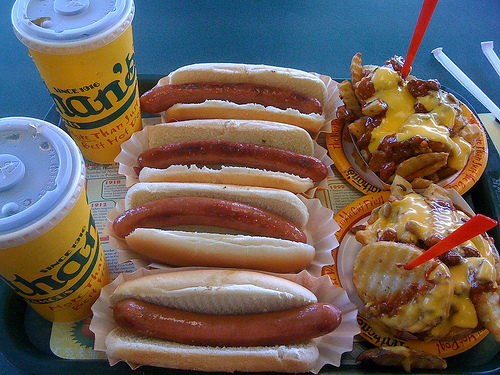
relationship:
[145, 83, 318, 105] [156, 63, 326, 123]
hot dog inside buns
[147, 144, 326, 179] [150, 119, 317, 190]
hot dog inside buns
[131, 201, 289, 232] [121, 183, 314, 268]
hot dog inside buns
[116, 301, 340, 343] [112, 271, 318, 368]
hot dog inside buns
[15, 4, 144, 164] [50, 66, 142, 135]
cup has writing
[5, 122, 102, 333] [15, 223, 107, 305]
cup has writing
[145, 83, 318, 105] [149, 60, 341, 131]
hot dog inside white wrapper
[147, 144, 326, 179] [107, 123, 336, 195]
hot dog inside white wrapper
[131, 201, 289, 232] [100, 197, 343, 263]
hot dog inside white wrapper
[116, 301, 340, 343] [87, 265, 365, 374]
hot dog inside white wrapper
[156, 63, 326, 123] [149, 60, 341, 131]
buns inside white wrapper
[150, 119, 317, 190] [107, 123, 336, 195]
buns inside white wrapper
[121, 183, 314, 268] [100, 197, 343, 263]
buns inside white wrapper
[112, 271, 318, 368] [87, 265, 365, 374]
buns inside white wrapper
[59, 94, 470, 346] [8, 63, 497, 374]
food and drinks are on top of a tray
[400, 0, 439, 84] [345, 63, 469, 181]
fork stuck inside chilli fries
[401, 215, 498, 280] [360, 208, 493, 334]
fork stuck inside chilli fries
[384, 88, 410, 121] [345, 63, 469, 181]
cheese drizzled on top chilli fries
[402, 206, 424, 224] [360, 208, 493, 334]
cheese drizzled on top chilli fries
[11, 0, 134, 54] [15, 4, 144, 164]
lid on top of a cup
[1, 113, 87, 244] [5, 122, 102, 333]
lid on top of a cup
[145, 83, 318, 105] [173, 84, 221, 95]
hot dog has grill marks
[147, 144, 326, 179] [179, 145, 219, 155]
hot dog has grill marks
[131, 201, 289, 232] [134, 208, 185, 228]
hot dog has grill marks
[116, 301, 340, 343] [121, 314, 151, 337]
hot dog has grill marks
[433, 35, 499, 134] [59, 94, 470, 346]
straw wrappers are to right of food and drinks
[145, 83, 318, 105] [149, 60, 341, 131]
hot dog are on top of white wrapper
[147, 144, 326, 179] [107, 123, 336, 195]
hot dog are on top of white wrapper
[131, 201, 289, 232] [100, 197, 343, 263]
hot dog are on top of white wrapper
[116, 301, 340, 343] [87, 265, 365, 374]
hot dog are on top of white wrapper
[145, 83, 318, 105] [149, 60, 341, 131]
hot dog on top of white wrapper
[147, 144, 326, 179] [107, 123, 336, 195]
hot dog on top of white wrapper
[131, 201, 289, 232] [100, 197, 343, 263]
hot dog on top of white wrapper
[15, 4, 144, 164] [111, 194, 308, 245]
cup to left of hot dog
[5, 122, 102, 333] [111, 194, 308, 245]
cup to left of hot dog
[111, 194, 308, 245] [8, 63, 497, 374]
hot dog are on tray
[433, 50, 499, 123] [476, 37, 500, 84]
straw to left of straw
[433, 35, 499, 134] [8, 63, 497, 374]
straw wrappers are to right of tray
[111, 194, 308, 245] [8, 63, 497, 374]
hot dog are on top of a tray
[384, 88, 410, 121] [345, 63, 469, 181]
cheese are drizzled on top chilli fries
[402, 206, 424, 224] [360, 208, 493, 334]
cheese are drizzled on top chilli fries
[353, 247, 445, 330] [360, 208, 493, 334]
potato slice next to chilli fries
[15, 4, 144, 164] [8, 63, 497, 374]
cup on top of tray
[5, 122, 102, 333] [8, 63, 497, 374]
cup on top of tray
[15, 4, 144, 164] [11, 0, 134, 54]
cup has lid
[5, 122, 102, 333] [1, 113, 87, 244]
cup has lid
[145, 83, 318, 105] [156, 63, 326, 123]
hot dog resting on to of buns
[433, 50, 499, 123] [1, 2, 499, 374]
straw on top of table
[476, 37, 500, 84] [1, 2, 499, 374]
straw on top of table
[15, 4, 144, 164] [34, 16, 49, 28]
cup filled with soda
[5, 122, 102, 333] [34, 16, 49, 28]
cup filled with soda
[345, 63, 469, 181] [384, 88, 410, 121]
chilli fries covered with cheese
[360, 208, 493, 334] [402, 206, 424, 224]
chilli fries covered with cheese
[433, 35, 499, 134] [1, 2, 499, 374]
straw wrappers are on table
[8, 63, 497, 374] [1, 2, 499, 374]
tray on table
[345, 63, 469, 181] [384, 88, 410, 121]
chilli fries are covered in cheese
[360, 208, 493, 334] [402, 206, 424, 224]
chilli fries are covered in cheese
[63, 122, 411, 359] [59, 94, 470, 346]
paper menu underneath food and drinks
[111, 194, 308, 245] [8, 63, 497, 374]
hot dog are on top of tray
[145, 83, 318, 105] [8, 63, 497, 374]
hot dog on top of tray